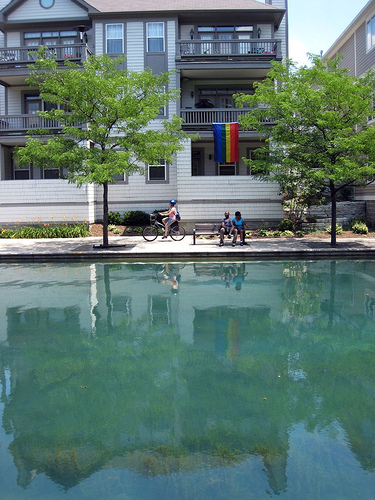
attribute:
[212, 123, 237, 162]
flag — colorful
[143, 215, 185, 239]
bicycle — black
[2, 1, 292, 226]
building — brown, white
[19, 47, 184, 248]
tree — green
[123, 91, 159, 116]
leaves — green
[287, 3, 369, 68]
sky — blue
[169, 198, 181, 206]
helmet — blue